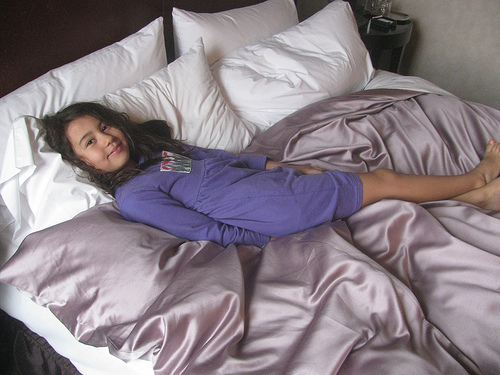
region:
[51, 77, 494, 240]
Little girl laying on bed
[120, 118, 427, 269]
Little girl wearing a purple nightgown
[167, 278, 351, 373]
the sheets are wrinkled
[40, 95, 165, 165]
The girl has dark hair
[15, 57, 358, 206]
pillows laying on the bed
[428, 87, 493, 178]
Little girl is not wearing shoes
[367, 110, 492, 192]
Little girl has her legs crossed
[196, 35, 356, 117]
The pillows are white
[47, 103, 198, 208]
Little girl is smiling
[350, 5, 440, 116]
Stand beside the bed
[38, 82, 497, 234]
young girl laying on a bed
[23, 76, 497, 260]
little girl with long brown hair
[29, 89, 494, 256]
little girl with curly hair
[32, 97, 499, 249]
little girl wearing purple nightclothes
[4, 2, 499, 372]
large fluffy bed with purple comforter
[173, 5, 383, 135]
two white fluffy pillows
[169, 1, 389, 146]
big pillows in white pillowcases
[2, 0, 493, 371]
bed with four pillows on top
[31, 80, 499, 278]
little girl laying on a white pillow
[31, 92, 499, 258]
little girl laying on a purple comforter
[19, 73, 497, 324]
little girl laying on a bed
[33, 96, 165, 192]
head resting on the pillow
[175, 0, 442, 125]
one pillow propped up against another pillow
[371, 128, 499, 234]
one leg laying over the other leg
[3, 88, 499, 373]
shiny light purple duvet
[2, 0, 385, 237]
four white pillows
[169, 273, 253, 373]
wrinkles in the duvet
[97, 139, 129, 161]
small smile, not showing teeth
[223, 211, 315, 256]
hand under the body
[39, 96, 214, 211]
long dark hair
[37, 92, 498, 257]
a still happy kid, maybe nine years old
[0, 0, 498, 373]
kid lies diagonally across parents', or maybe hotel, bed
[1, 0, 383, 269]
four head pillows, one bed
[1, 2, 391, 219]
@ least a couple of the pillows are king or queen size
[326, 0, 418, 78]
nightstand with a number of unintentionally cryptic items on it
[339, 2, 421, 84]
nightstand is black, w/ thin legs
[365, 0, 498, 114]
shadow of nightstand on light grey purposely mottled wall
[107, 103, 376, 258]
kid wears purple dress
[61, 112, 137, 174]
kid also wears an early attempt at a sophisticated expression. plenty of time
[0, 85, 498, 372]
really nice mauve satin bedding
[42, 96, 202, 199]
the girl is smiling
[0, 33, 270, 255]
this is a pillow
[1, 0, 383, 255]
the pillow is white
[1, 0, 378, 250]
there are many pillows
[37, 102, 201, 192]
the girl has dark hair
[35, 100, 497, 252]
the girl is lying down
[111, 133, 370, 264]
the girl is wearing a dress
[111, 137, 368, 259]
the girl's dress is blue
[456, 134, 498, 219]
the girl is barefooted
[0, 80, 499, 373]
the comforter is on the bed